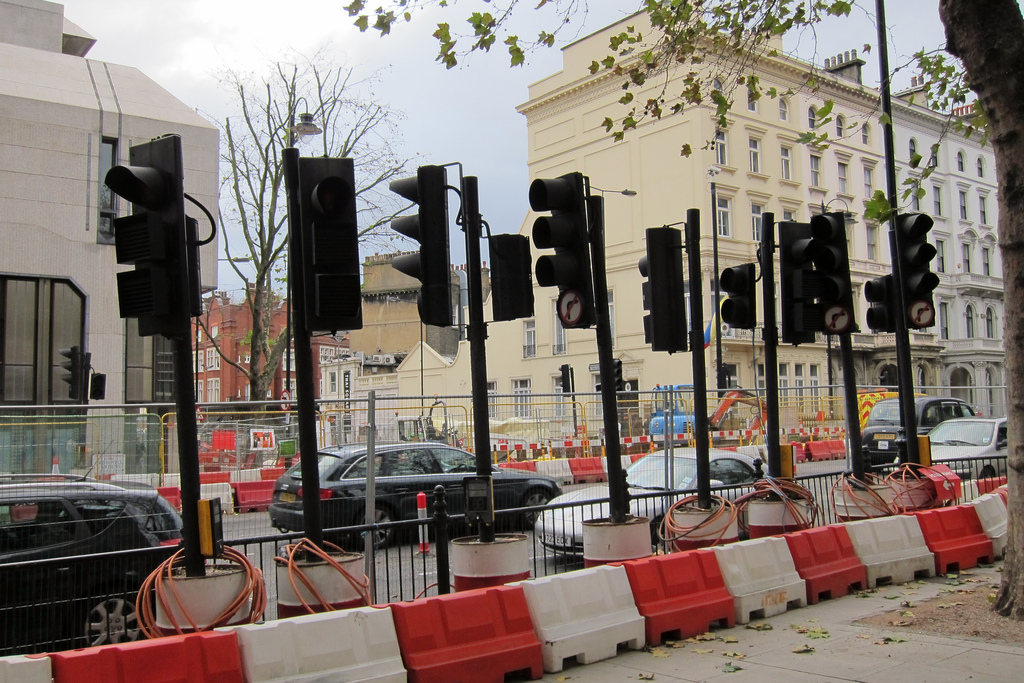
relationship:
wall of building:
[323, 5, 715, 476] [323, 6, 890, 464]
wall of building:
[356, 285, 415, 346] [333, 248, 500, 389]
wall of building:
[345, 328, 529, 503] [345, 151, 529, 503]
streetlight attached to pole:
[89, 140, 230, 344] [89, 140, 230, 489]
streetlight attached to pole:
[277, 184, 386, 301] [277, 184, 386, 513]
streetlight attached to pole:
[401, 156, 545, 330] [401, 156, 545, 542]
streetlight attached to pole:
[632, 238, 732, 368] [632, 238, 732, 368]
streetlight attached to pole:
[512, 180, 633, 302] [512, 180, 633, 491]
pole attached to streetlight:
[512, 180, 633, 491] [512, 180, 633, 302]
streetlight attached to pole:
[702, 263, 792, 361] [702, 237, 792, 490]